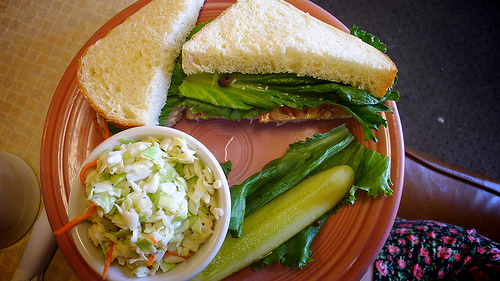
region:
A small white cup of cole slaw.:
[66, 123, 231, 279]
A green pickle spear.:
[200, 163, 357, 280]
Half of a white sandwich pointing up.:
[76, 1, 201, 127]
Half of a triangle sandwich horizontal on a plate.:
[177, 0, 397, 121]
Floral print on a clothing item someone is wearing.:
[372, 212, 499, 279]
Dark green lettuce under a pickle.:
[221, 123, 397, 268]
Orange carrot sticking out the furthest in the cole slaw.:
[53, 203, 101, 234]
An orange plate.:
[39, 2, 404, 279]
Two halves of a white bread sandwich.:
[76, 0, 397, 127]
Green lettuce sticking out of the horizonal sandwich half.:
[179, 23, 399, 139]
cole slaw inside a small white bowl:
[66, 125, 231, 280]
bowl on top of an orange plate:
[42, 1, 405, 279]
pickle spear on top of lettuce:
[196, 163, 353, 277]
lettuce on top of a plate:
[224, 123, 393, 266]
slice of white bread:
[181, 0, 394, 95]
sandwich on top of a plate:
[76, 0, 398, 142]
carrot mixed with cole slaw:
[51, 201, 95, 236]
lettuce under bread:
[178, 70, 394, 143]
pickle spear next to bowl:
[194, 162, 357, 279]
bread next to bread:
[182, 0, 397, 100]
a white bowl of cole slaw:
[63, 124, 228, 279]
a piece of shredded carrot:
[54, 202, 92, 235]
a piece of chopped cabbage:
[90, 187, 115, 211]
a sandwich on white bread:
[82, 0, 393, 124]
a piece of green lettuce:
[181, 68, 384, 137]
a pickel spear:
[194, 163, 355, 279]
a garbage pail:
[1, 151, 39, 252]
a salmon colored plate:
[43, 0, 400, 280]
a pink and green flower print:
[374, 212, 498, 280]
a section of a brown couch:
[393, 152, 498, 238]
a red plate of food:
[28, 17, 449, 279]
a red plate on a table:
[45, 8, 442, 273]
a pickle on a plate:
[218, 162, 379, 279]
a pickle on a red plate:
[203, 172, 383, 278]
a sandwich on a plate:
[48, 3, 434, 166]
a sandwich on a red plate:
[67, 3, 457, 180]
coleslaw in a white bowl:
[46, 118, 261, 279]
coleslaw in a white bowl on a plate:
[34, 103, 278, 280]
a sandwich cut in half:
[37, 3, 409, 137]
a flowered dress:
[318, 155, 495, 275]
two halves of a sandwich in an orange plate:
[76, 0, 394, 128]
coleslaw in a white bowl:
[61, 125, 231, 279]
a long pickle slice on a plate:
[199, 158, 357, 280]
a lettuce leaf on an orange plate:
[223, 125, 391, 277]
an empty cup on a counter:
[0, 148, 43, 253]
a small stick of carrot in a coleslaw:
[52, 207, 97, 234]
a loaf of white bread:
[186, 0, 397, 94]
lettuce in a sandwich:
[178, 25, 400, 142]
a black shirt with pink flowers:
[367, 211, 499, 278]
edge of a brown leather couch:
[400, 145, 499, 246]